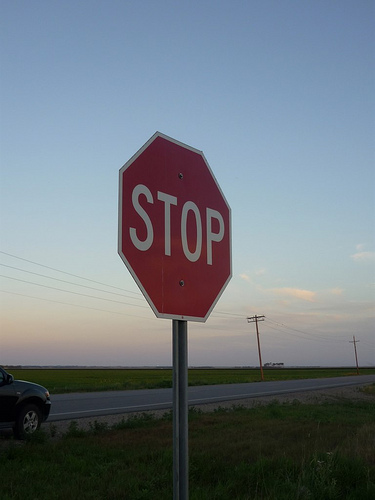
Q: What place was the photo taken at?
A: It was taken at the field.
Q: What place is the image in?
A: It is at the field.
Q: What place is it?
A: It is a field.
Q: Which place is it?
A: It is a field.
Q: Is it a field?
A: Yes, it is a field.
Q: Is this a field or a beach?
A: It is a field.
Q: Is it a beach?
A: No, it is a field.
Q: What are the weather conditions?
A: It is clear.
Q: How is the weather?
A: It is clear.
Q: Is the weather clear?
A: Yes, it is clear.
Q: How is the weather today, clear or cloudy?
A: It is clear.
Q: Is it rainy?
A: No, it is clear.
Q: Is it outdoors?
A: Yes, it is outdoors.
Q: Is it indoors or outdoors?
A: It is outdoors.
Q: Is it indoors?
A: No, it is outdoors.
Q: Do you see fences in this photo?
A: No, there are no fences.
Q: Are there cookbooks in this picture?
A: No, there are no cookbooks.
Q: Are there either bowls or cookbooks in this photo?
A: No, there are no cookbooks or bowls.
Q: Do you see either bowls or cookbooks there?
A: No, there are no cookbooks or bowls.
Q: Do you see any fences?
A: No, there are no fences.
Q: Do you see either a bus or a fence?
A: No, there are no fences or buses.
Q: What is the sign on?
A: The sign is on the pole.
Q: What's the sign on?
A: The sign is on the pole.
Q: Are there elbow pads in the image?
A: No, there are no elbow pads.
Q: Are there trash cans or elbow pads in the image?
A: No, there are no elbow pads or trash cans.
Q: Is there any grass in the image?
A: Yes, there is grass.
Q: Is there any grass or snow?
A: Yes, there is grass.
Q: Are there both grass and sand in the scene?
A: No, there is grass but no sand.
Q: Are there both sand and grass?
A: No, there is grass but no sand.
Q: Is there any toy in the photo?
A: No, there are no toys.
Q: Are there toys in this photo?
A: No, there are no toys.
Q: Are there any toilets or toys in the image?
A: No, there are no toys or toilets.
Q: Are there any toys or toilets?
A: No, there are no toys or toilets.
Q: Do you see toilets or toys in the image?
A: No, there are no toys or toilets.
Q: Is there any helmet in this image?
A: No, there are no helmets.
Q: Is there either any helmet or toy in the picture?
A: No, there are no helmets or toys.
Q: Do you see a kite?
A: No, there are no kites.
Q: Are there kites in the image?
A: No, there are no kites.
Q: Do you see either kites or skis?
A: No, there are no kites or skis.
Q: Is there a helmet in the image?
A: No, there are no helmets.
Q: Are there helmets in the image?
A: No, there are no helmets.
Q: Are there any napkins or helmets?
A: No, there are no helmets or napkins.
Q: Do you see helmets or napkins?
A: No, there are no helmets or napkins.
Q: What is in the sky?
A: The clouds are in the sky.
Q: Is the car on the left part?
A: Yes, the car is on the left of the image.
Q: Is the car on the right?
A: No, the car is on the left of the image.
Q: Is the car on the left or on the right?
A: The car is on the left of the image.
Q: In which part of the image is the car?
A: The car is on the left of the image.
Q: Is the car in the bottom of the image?
A: Yes, the car is in the bottom of the image.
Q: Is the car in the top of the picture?
A: No, the car is in the bottom of the image.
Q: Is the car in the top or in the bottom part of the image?
A: The car is in the bottom of the image.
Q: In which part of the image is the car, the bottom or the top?
A: The car is in the bottom of the image.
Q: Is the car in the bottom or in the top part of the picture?
A: The car is in the bottom of the image.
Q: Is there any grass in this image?
A: Yes, there is grass.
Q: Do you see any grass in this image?
A: Yes, there is grass.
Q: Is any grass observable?
A: Yes, there is grass.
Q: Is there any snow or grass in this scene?
A: Yes, there is grass.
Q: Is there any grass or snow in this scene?
A: Yes, there is grass.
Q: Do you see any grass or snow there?
A: Yes, there is grass.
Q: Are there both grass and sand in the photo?
A: No, there is grass but no sand.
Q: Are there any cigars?
A: No, there are no cigars.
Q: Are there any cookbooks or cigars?
A: No, there are no cigars or cookbooks.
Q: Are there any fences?
A: No, there are no fences.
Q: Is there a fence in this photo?
A: No, there are no fences.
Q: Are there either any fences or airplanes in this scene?
A: No, there are no fences or airplanes.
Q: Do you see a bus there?
A: No, there are no buses.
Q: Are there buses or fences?
A: No, there are no buses or fences.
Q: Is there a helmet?
A: No, there are no helmets.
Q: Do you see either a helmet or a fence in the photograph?
A: No, there are no helmets or fences.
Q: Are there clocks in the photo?
A: No, there are no clocks.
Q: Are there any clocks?
A: No, there are no clocks.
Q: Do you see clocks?
A: No, there are no clocks.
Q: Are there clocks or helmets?
A: No, there are no clocks or helmets.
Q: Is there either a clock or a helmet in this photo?
A: No, there are no clocks or helmets.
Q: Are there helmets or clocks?
A: No, there are no clocks or helmets.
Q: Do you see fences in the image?
A: No, there are no fences.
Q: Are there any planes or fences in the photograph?
A: No, there are no fences or planes.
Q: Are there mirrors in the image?
A: No, there are no mirrors.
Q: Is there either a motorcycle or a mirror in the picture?
A: No, there are no mirrors or motorcycles.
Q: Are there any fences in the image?
A: No, there are no fences.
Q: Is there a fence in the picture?
A: No, there are no fences.